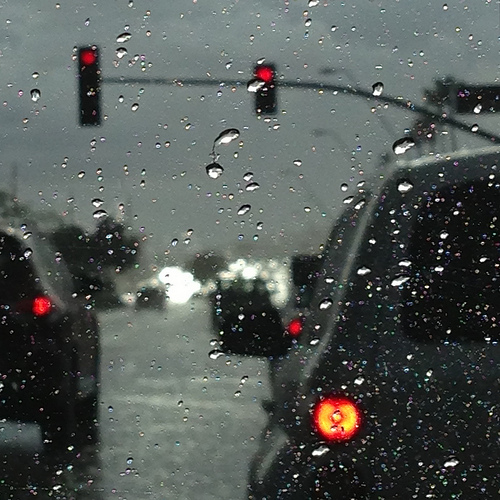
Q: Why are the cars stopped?
A: The light is red.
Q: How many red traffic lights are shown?
A: Two.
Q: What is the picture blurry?
A: Its raining.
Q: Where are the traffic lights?
A: Above the cars.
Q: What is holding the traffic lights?
A: A pole.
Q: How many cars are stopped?
A: Three.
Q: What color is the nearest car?
A: Gray.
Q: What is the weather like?
A: Rainy.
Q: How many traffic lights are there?
A: 2.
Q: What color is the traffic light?
A: Red.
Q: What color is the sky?
A: Gray.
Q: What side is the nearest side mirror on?
A: Driver's side.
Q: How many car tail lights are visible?
A: 2.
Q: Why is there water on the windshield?
A: It's raining.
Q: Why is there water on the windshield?
A: It's raining.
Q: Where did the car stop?
A: Red light.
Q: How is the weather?
A: Dark and cloudy.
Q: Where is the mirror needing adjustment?
A: On the side of the car.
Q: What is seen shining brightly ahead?
A: Headlights of car.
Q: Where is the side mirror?
A: Side of car.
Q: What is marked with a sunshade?
A: Window.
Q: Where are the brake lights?
A: In the rear.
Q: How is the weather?
A: Raining.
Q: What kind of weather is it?
A: Rainy.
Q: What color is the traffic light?
A: Red.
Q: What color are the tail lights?
A: Red.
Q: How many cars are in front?
A: 2.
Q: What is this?
A: Cars.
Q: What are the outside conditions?
A: Raining.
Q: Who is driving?
A: Professors.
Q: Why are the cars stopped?
A: Red light.